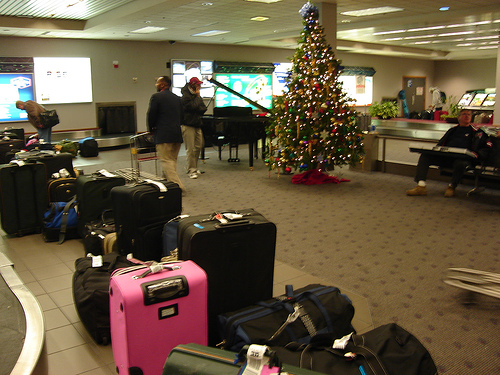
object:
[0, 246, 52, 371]
carousel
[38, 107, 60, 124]
bag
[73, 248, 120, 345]
bag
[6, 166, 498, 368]
ground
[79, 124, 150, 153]
conveyor belt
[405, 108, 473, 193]
down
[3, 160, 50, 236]
bag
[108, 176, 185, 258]
bag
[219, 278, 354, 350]
bag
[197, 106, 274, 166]
piano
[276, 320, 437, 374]
bag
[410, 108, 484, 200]
man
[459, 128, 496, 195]
bench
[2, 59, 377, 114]
bill boards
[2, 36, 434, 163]
wall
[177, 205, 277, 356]
bag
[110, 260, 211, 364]
suitcase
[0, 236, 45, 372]
carousel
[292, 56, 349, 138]
ornaments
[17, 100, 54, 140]
man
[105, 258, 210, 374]
bag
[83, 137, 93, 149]
hat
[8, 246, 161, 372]
ground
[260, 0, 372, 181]
tree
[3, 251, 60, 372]
carousel